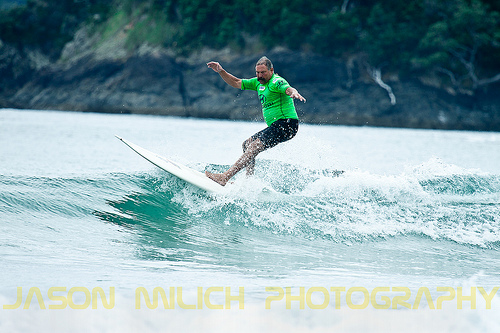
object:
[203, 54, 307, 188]
man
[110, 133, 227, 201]
surfboard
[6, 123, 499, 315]
ocean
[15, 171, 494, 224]
wave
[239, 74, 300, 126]
shirt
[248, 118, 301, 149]
shorts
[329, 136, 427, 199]
water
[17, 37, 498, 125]
cliff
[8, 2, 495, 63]
trees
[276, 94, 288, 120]
stripe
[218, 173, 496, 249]
foam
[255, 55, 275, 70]
hair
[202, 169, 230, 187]
feet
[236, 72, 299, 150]
wet suit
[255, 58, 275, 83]
head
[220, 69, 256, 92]
arm